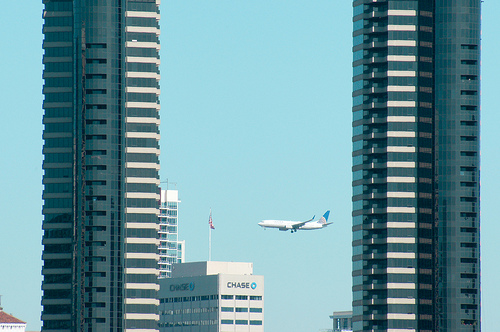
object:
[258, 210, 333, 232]
plane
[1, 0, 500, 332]
sky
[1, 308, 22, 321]
roof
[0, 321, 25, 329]
residence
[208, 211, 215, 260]
flag pole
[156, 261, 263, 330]
bank